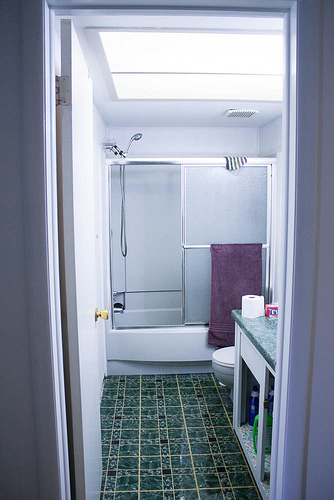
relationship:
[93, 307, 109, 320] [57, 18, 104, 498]
handle of door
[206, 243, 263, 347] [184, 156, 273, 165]
towel hanging rod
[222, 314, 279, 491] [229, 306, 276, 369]
cabinet under sink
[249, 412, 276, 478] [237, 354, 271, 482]
items underneath cabinet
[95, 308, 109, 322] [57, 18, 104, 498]
handle on a door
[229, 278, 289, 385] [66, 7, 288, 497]
counter in bathroom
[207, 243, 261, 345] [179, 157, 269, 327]
towel hanging shower door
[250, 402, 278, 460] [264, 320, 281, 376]
green bottle under sink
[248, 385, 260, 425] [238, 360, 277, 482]
cleaning supply below sink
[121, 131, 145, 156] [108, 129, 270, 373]
shower head in shower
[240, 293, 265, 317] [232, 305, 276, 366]
toilet paper roll on counter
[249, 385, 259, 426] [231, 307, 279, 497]
cleaning supply under sink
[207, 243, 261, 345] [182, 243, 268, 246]
towel hanging down from rack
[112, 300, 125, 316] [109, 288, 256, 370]
nozzel for tub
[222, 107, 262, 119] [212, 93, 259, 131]
vent on ceiling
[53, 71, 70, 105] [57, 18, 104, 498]
bracket on door